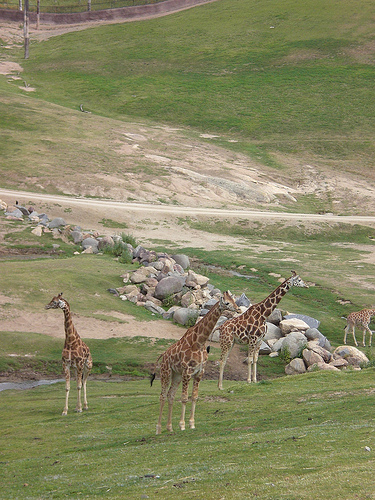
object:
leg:
[154, 374, 169, 433]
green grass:
[8, 4, 368, 495]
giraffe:
[343, 294, 373, 362]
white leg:
[62, 369, 73, 418]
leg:
[188, 376, 200, 430]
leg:
[178, 380, 189, 432]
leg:
[216, 360, 230, 392]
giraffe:
[208, 266, 311, 400]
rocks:
[329, 338, 370, 374]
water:
[4, 354, 88, 393]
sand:
[0, 304, 27, 333]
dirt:
[74, 117, 372, 219]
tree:
[18, 0, 37, 55]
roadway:
[2, 184, 374, 238]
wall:
[0, 0, 193, 28]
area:
[2, 11, 374, 493]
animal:
[213, 267, 317, 392]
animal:
[150, 286, 237, 438]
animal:
[44, 292, 95, 414]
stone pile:
[122, 256, 366, 380]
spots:
[182, 344, 192, 366]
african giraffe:
[148, 282, 246, 436]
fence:
[2, 3, 195, 32]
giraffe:
[152, 283, 244, 434]